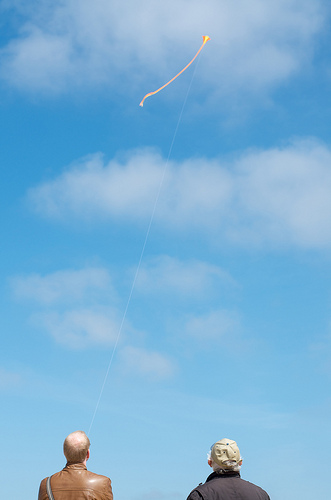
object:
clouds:
[14, 242, 250, 378]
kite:
[138, 35, 210, 109]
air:
[5, 5, 124, 118]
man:
[37, 429, 113, 499]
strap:
[45, 475, 56, 500]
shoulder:
[39, 477, 48, 493]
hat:
[210, 438, 243, 468]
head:
[207, 438, 243, 472]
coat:
[38, 462, 115, 499]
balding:
[66, 430, 88, 448]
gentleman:
[35, 429, 113, 498]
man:
[186, 439, 271, 500]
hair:
[63, 430, 91, 462]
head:
[63, 430, 91, 463]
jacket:
[36, 462, 115, 499]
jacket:
[187, 471, 270, 500]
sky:
[0, 0, 331, 116]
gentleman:
[184, 437, 276, 500]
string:
[84, 44, 207, 438]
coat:
[185, 471, 270, 499]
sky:
[14, 258, 302, 387]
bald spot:
[75, 441, 82, 447]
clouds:
[26, 135, 331, 255]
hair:
[207, 450, 242, 472]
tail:
[138, 45, 204, 107]